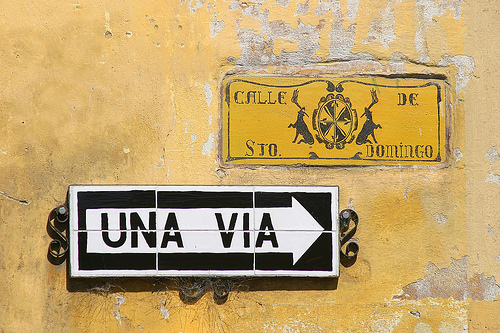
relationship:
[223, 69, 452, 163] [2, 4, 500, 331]
sign on building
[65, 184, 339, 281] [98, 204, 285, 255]
sign says una via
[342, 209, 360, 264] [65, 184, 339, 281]
embellishment on sign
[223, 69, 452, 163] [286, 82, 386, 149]
sign has emblem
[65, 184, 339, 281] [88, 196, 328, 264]
sign has arrow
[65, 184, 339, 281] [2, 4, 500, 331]
sign on building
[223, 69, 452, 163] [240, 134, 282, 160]
sign has text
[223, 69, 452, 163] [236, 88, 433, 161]
sign says calle de sto domingo